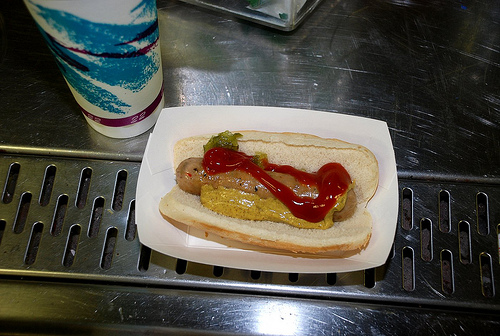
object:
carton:
[134, 105, 400, 274]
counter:
[0, 0, 500, 336]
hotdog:
[175, 157, 357, 222]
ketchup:
[202, 147, 353, 223]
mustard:
[200, 180, 358, 230]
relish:
[203, 130, 268, 170]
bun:
[157, 129, 380, 254]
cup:
[19, 0, 164, 140]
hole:
[36, 163, 56, 207]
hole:
[74, 167, 94, 210]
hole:
[111, 168, 129, 213]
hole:
[400, 187, 414, 232]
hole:
[439, 189, 452, 234]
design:
[22, 0, 165, 127]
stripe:
[77, 80, 165, 127]